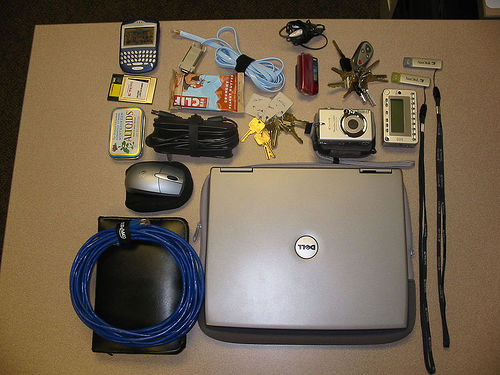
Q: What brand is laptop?
A: Dell.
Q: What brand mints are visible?
A: Altoids.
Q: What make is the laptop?
A: Dell.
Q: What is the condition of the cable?
A: Rolled up.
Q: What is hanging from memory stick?
A: Tags.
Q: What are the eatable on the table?
A: A Chewing Gum and an energy bar.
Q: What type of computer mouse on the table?
A: Codeless.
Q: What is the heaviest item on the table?
A: Laptop.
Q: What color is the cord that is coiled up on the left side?
A: Blue.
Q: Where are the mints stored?
A: In the tin.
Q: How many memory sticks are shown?
A: Two.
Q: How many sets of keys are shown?
A: Two.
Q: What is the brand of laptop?
A: Dell.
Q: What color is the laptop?
A: Silver.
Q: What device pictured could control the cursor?
A: A mouse.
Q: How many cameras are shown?
A: One.